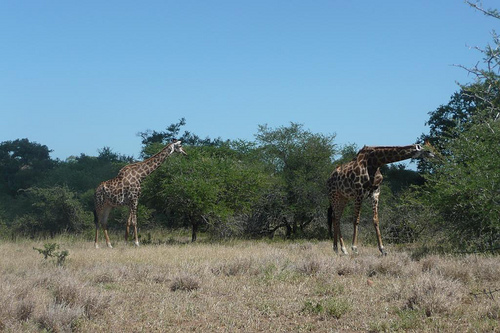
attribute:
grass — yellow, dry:
[8, 232, 483, 326]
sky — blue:
[14, 9, 474, 183]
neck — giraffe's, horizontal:
[367, 138, 422, 174]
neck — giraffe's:
[359, 137, 418, 177]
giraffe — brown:
[76, 122, 226, 251]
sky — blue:
[27, 15, 475, 169]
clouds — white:
[49, 22, 450, 124]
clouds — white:
[33, 29, 462, 92]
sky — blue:
[14, 27, 477, 116]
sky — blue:
[8, 22, 484, 119]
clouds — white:
[12, 12, 452, 162]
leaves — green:
[240, 136, 305, 212]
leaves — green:
[146, 126, 299, 239]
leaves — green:
[423, 120, 468, 190]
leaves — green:
[425, 101, 485, 195]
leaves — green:
[44, 156, 85, 190]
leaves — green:
[20, 130, 75, 245]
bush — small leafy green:
[28, 224, 67, 275]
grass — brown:
[104, 232, 321, 326]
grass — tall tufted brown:
[96, 223, 442, 313]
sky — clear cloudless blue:
[89, 17, 344, 120]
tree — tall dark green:
[10, 126, 72, 221]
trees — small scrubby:
[235, 103, 335, 243]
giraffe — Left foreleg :
[310, 119, 447, 285]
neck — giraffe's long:
[364, 144, 400, 164]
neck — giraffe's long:
[359, 137, 420, 159]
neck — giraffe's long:
[125, 148, 169, 180]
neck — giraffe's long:
[134, 145, 182, 182]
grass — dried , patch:
[289, 287, 356, 331]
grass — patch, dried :
[289, 270, 350, 330]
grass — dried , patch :
[206, 251, 306, 307]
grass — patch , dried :
[146, 267, 232, 324]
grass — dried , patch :
[179, 261, 259, 318]